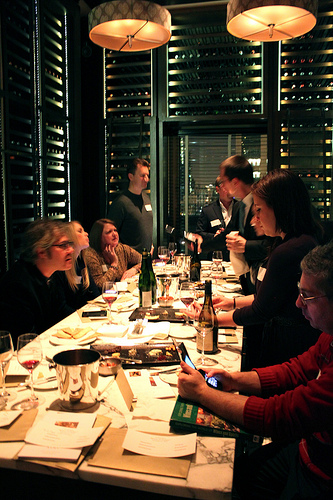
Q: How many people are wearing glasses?
A: Two.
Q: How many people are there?
A: Eight.